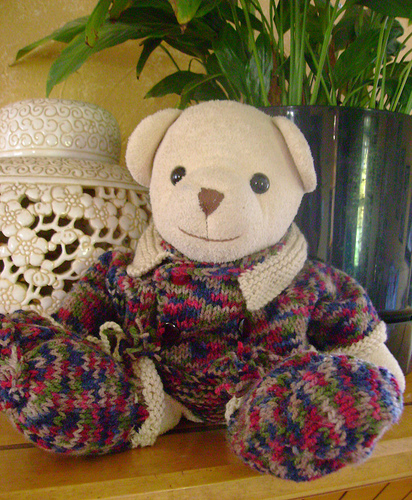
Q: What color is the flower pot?
A: Blue.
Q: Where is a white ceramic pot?
A: Behind stuffed animal on left.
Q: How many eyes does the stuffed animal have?
A: Two.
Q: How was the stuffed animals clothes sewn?
A: Crocheted.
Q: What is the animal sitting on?
A: Table.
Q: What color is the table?
A: Brown.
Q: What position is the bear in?
A: Sitting position.